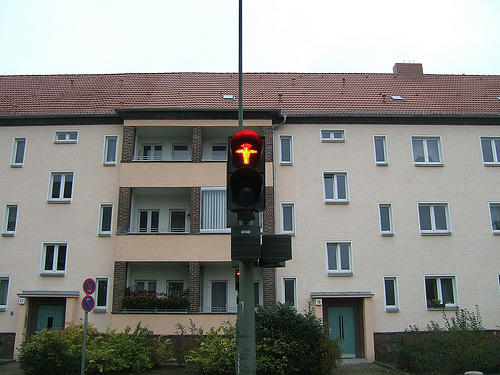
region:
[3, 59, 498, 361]
apartment building with tile roof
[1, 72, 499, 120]
red tile roof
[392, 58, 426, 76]
chimney on roof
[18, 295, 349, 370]
green shubbery in front of building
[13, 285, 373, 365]
two entrances to building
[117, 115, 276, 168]
balcony of third-floor apartment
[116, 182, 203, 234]
balcony of second-floor apartment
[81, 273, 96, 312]
red and blue signs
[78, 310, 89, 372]
metal pole supporting blue and red signs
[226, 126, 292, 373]
red traffic light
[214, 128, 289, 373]
Traffic light in front of building.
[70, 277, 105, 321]
Red and blue traffic sign.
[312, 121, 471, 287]
Windows in front of building.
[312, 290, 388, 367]
Door in front of building.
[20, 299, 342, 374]
Shrubbery growing in front of building.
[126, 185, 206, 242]
Balcony on front of building.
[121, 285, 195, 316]
Flowers growing on balcony.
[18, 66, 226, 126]
Red tiled roof on building.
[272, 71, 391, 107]
Heat vents on top of building.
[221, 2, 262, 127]
Rod extending from top of traffic light.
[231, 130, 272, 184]
a stop sign signal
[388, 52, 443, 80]
a chimney on top of the house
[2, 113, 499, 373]
a house with a lot of windows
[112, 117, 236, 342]
a house with three balcons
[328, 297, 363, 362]
a green door for the house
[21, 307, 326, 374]
flowers outside the building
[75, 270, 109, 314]
a restriction sign outside the building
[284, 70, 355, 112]
a brown roof on the building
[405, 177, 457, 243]
transparent window on the building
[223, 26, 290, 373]
a tall post holding the traffic light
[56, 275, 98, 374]
Road signs on silver pole.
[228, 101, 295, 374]
Traffic signal with red light lit.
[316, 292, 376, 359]
Green double door on building.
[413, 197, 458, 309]
Windows on a tall building.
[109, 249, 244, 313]
Balcony with greenery and brick pillars.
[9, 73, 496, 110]
Red tile roof with skylights.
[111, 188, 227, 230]
Balcony with white window shades.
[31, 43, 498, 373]
Big building with lots of windows.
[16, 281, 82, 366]
Green double door with window.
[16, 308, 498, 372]
Bushes on side of street.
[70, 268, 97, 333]
red and blue sign along street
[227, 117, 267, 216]
stoplight on the poke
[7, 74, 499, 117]
red shingle roof on building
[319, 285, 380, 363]
green door on apartment building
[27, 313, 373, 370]
green bushes along building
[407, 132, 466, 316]
row of apartment windows on building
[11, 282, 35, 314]
apartment number on door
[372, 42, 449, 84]
red brick chimney on roof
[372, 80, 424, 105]
skylights in the roof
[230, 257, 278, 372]
green metal pole for light